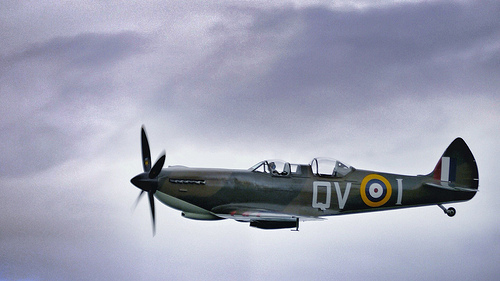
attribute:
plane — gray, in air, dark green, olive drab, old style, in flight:
[130, 125, 479, 236]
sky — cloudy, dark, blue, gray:
[1, 0, 498, 280]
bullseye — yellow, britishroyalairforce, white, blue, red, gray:
[359, 174, 392, 208]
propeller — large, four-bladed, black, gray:
[131, 125, 166, 238]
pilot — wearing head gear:
[267, 163, 279, 177]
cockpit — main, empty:
[250, 159, 300, 178]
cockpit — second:
[310, 158, 354, 177]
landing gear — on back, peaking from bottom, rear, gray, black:
[438, 204, 456, 218]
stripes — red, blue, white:
[433, 157, 458, 182]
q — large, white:
[312, 181, 331, 213]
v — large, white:
[334, 181, 352, 211]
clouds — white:
[1, 0, 499, 280]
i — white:
[394, 177, 404, 207]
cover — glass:
[312, 159, 340, 176]